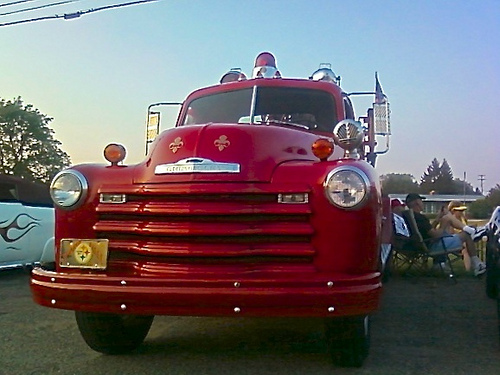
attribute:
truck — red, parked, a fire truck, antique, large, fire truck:
[27, 49, 396, 368]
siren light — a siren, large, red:
[254, 52, 280, 79]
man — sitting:
[400, 191, 482, 280]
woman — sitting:
[439, 196, 499, 275]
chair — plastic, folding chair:
[393, 207, 457, 283]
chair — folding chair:
[437, 227, 489, 287]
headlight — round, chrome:
[47, 167, 91, 213]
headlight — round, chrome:
[324, 163, 372, 216]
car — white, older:
[2, 173, 75, 269]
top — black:
[1, 176, 62, 211]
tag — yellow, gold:
[55, 233, 112, 271]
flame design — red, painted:
[1, 212, 45, 243]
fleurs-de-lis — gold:
[167, 138, 187, 151]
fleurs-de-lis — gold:
[212, 135, 232, 154]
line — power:
[1, 0, 78, 15]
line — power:
[1, 2, 32, 11]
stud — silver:
[329, 307, 335, 314]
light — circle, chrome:
[218, 74, 249, 84]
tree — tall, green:
[2, 97, 73, 206]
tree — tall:
[422, 156, 441, 194]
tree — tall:
[434, 157, 455, 195]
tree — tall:
[458, 177, 480, 195]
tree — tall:
[380, 173, 419, 194]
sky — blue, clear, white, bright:
[2, 2, 498, 199]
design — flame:
[1, 216, 40, 254]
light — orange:
[102, 144, 128, 165]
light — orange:
[309, 140, 338, 164]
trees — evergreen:
[414, 160, 458, 193]